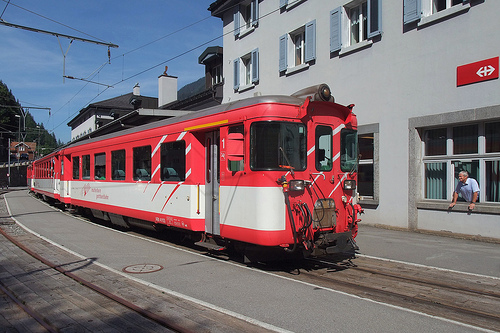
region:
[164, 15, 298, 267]
the train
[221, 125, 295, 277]
the train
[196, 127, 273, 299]
the train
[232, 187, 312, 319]
the train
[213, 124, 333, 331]
the train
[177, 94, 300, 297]
a train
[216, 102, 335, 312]
a train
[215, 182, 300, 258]
a train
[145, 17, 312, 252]
a train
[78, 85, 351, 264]
a red and white trolley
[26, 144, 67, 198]
a red and white trolley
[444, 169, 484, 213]
a man hanging out window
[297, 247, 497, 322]
a set of trolley tracks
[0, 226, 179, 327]
a set of trolley tracks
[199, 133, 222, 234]
a trolley entry doors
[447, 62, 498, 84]
a red directional sign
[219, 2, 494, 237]
a large white building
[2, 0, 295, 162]
overhead electrical wires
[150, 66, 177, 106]
a white and black chimney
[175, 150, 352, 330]
a train is visibe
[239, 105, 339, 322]
a train is visibe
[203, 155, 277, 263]
a train is visibe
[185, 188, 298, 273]
a train is visibe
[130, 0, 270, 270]
a train is visibe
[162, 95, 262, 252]
the train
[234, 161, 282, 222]
the train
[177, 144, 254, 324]
the train